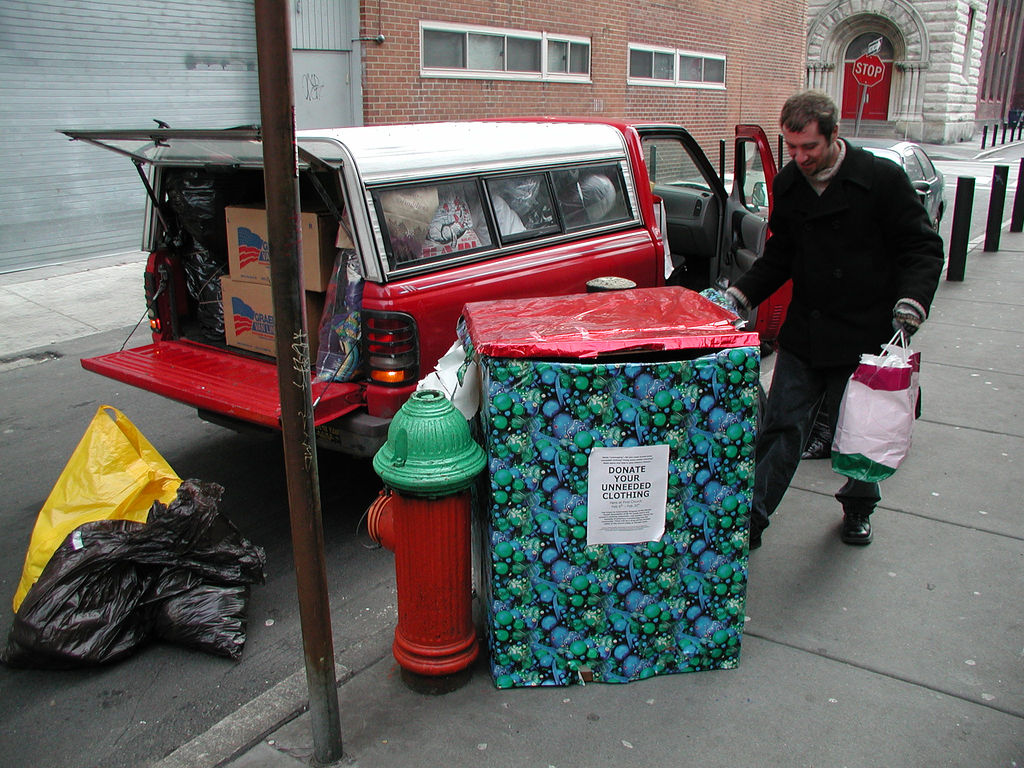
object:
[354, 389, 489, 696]
hydrant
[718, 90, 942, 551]
man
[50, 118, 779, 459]
truck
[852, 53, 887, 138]
sign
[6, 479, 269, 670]
bags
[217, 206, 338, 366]
boxes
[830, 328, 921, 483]
bag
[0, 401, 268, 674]
pile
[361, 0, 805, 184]
building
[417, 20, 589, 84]
windows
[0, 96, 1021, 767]
street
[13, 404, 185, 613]
bag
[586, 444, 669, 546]
paper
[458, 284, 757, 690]
box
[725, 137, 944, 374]
coat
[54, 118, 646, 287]
camper shell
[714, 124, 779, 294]
door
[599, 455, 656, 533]
black lettering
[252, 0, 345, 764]
pole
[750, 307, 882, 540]
pants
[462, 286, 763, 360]
top of box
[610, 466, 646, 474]
donating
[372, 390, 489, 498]
hydrant top